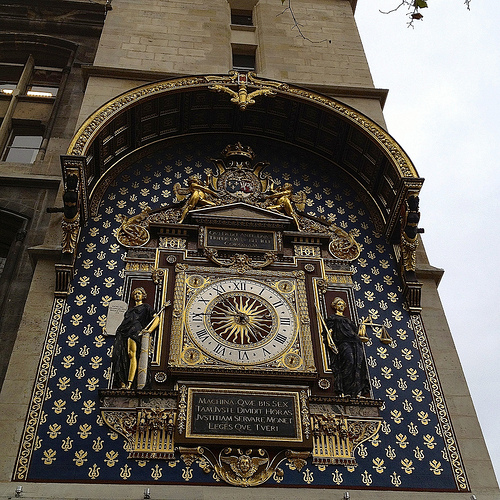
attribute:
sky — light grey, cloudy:
[416, 92, 481, 192]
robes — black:
[112, 302, 368, 392]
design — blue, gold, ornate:
[9, 59, 473, 492]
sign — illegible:
[201, 222, 278, 251]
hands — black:
[202, 299, 260, 341]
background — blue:
[377, 352, 427, 454]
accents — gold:
[31, 125, 428, 460]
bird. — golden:
[208, 76, 276, 111]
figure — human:
[312, 296, 393, 398]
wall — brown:
[279, 17, 339, 79]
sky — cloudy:
[446, 47, 495, 126]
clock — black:
[197, 264, 317, 351]